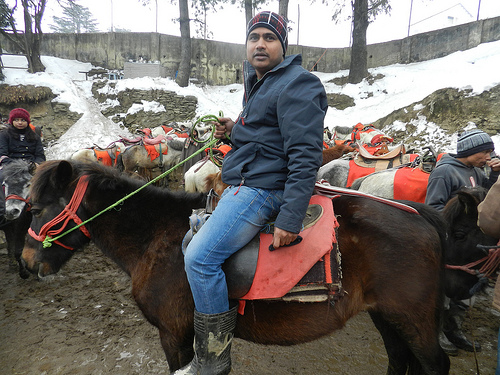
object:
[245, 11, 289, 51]
cap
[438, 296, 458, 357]
boot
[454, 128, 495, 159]
hat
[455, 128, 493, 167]
head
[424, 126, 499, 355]
man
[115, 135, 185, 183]
animal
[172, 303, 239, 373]
boot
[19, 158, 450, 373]
horse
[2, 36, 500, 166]
snow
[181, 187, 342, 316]
saddle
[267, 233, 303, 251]
object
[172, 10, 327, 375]
man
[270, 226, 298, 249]
hand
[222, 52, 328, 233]
coat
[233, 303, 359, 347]
stomach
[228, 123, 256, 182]
stomach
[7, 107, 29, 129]
head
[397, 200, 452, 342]
tail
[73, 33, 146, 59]
wall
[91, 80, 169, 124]
hill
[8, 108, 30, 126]
cap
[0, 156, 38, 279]
horse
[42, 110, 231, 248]
green rope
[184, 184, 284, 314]
jeans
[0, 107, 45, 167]
person